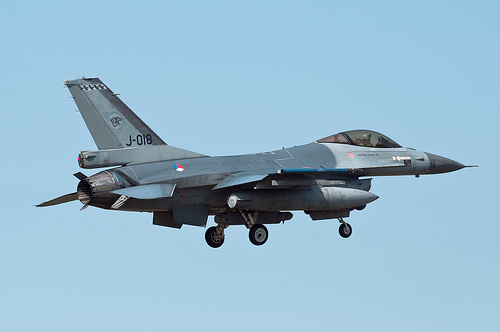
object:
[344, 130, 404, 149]
whindshield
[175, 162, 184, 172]
logo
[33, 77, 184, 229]
back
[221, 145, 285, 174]
middle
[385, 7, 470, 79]
sky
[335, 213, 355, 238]
wheel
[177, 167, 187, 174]
circle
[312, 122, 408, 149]
window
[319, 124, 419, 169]
cockpit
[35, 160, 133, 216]
engine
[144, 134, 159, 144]
writing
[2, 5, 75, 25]
air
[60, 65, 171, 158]
tail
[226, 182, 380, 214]
missile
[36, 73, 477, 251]
airplane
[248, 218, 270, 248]
wheel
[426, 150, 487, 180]
nose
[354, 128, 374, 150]
pilot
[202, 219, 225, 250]
wheel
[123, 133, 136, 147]
letters